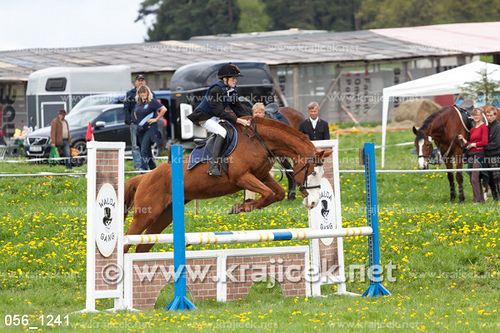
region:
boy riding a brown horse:
[123, 45, 323, 227]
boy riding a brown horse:
[125, 63, 354, 240]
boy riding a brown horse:
[122, 59, 332, 242]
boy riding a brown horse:
[115, 29, 366, 243]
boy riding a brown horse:
[130, 65, 348, 250]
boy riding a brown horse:
[108, 46, 344, 246]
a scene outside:
[3, 11, 497, 325]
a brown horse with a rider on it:
[106, 49, 344, 273]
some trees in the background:
[126, 0, 498, 55]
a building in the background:
[3, 19, 498, 144]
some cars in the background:
[6, 41, 331, 179]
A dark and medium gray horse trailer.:
[25, 64, 132, 130]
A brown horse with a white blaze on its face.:
[410, 104, 495, 204]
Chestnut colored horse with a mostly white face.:
[298, 145, 333, 209]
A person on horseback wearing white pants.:
[187, 62, 252, 179]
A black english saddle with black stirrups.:
[192, 118, 234, 178]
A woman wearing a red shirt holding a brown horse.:
[411, 103, 488, 205]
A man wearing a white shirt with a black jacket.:
[297, 100, 331, 140]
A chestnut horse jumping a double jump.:
[68, 114, 390, 316]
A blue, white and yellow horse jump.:
[163, 143, 392, 312]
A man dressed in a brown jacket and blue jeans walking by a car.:
[46, 108, 81, 170]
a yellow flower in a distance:
[460, 222, 477, 259]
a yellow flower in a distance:
[422, 251, 442, 272]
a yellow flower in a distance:
[400, 251, 415, 278]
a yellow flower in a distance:
[24, 235, 30, 245]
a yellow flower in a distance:
[35, 228, 51, 254]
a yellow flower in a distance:
[66, 248, 78, 268]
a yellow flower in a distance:
[236, 314, 248, 331]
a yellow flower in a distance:
[180, 310, 197, 327]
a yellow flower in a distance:
[301, 303, 326, 328]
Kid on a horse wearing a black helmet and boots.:
[185, 62, 251, 176]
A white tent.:
[377, 61, 499, 168]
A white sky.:
[2, 2, 154, 51]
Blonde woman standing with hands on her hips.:
[130, 85, 167, 172]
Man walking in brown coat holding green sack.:
[50, 109, 74, 169]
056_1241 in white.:
[2, 312, 69, 330]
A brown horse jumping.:
[122, 113, 334, 253]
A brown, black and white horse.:
[412, 105, 497, 203]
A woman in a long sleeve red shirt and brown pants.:
[457, 106, 489, 205]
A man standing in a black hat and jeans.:
[124, 74, 156, 171]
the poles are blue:
[170, 145, 396, 312]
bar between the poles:
[181, 230, 386, 295]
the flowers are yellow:
[22, 192, 83, 296]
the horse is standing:
[418, 103, 483, 195]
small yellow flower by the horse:
[398, 255, 408, 265]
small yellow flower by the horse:
[423, 249, 432, 254]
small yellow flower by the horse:
[454, 237, 464, 245]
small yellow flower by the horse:
[400, 230, 406, 235]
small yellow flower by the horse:
[383, 214, 390, 221]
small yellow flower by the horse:
[66, 265, 78, 275]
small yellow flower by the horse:
[48, 250, 54, 256]